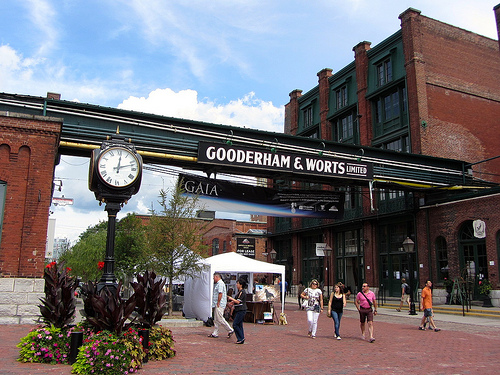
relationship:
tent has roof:
[182, 252, 285, 324] [193, 247, 283, 275]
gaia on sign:
[183, 180, 218, 196] [193, 139, 377, 183]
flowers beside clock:
[17, 314, 180, 375] [83, 135, 146, 200]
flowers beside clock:
[22, 317, 84, 369] [83, 135, 146, 200]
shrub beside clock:
[123, 269, 177, 350] [83, 135, 146, 200]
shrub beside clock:
[80, 263, 133, 338] [83, 135, 146, 200]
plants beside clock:
[32, 259, 79, 327] [83, 135, 146, 200]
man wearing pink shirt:
[352, 280, 384, 342] [353, 288, 375, 314]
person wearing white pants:
[300, 279, 324, 339] [305, 308, 319, 335]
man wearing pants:
[208, 270, 239, 340] [204, 299, 244, 334]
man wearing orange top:
[417, 275, 444, 332] [406, 280, 459, 311]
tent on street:
[134, 239, 203, 307] [4, 310, 498, 373]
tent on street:
[184, 252, 290, 324] [4, 310, 498, 373]